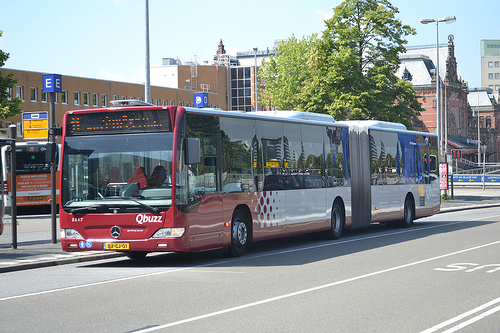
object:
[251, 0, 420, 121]
green trees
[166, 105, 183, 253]
edge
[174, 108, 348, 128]
edge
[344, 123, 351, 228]
edge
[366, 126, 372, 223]
edge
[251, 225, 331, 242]
edge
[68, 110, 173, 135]
display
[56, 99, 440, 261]
bus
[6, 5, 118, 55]
sky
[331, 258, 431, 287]
stripes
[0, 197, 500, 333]
road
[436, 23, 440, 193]
pole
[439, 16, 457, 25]
street lights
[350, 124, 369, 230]
connecting piece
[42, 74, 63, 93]
sign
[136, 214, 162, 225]
qbuzz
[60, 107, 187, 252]
bus front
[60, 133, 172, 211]
front window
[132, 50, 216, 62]
sky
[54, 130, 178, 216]
windshield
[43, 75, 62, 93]
cube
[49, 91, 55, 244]
pole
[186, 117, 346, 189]
reflection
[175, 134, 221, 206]
window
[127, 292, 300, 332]
line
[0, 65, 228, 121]
building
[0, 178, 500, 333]
area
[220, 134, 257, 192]
window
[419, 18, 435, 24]
lights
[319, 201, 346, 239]
wheel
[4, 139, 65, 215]
bus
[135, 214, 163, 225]
word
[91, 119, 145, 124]
information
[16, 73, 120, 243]
bus stop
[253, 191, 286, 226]
design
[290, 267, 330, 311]
part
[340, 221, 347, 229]
part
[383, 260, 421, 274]
part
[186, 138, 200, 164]
mirror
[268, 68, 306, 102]
foliage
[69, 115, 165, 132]
bus route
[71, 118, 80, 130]
number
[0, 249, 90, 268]
sidewalk